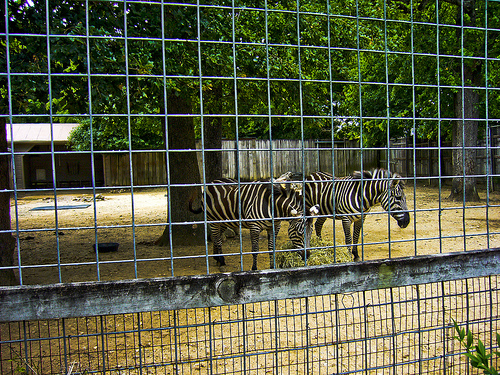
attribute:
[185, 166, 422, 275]
zebras — standing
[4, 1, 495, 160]
fence — enclosing area, blue, black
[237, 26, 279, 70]
leaves — green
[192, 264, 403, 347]
ground — brown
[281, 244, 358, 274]
grass — green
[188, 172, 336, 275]
zebra — black, white, eating grass, eating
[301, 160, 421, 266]
zebra — not eating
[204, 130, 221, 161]
woods — grey color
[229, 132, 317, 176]
board — weathered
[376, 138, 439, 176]
gate — gray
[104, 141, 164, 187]
fence — weathered, grey